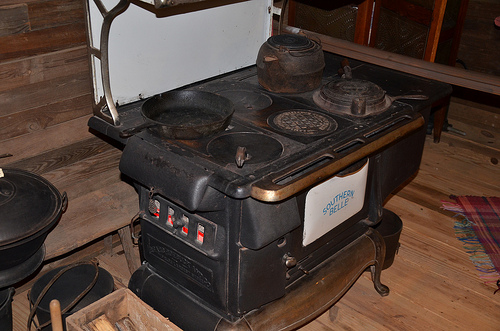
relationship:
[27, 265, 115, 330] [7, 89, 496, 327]
pot on top of floor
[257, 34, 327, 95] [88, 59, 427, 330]
tea kettle on top of stove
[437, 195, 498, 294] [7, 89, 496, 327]
rug on top of floor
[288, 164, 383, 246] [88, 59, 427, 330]
words on stove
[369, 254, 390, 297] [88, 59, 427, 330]
feet on stove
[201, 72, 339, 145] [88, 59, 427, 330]
burners on stove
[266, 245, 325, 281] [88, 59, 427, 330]
control on stove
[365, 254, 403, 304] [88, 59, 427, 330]
feet on stove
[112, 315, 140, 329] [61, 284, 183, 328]
firewood lying inside container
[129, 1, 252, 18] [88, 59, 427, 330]
rack hanging above stove